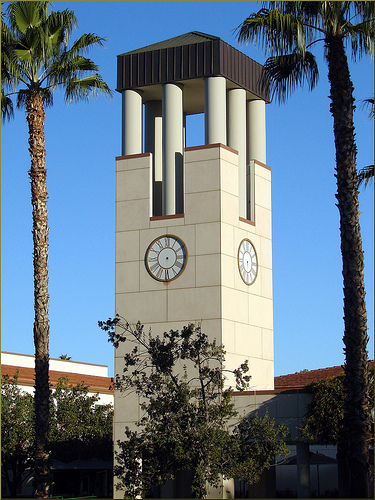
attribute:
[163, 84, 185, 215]
column — white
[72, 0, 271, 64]
sky — blue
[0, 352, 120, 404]
building — white, brown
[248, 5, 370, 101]
palm tree — tall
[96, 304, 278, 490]
tree — green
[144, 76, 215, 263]
pillar — white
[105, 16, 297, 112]
roof — brown, tile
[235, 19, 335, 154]
leaf — palm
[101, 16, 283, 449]
tower — clock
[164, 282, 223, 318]
brick — large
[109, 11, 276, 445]
tower — clock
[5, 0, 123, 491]
tree — palm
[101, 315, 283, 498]
tree — leafy, green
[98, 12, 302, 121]
roof — brown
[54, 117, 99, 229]
sky — clear, blue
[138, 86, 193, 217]
pillar — tall, round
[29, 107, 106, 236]
sky — cloudless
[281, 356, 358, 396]
roof — red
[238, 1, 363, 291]
tree — tall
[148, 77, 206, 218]
column — grey